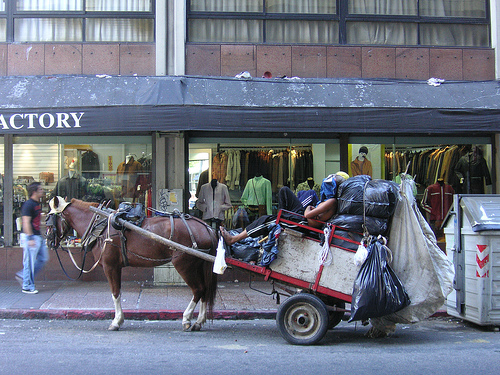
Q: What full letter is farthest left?
A: C.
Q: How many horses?
A: 1.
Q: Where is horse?
A: In front of the cart.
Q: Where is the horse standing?
A: The street.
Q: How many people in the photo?
A: 2.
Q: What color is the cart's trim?
A: Red.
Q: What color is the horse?
A: Brown.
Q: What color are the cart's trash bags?
A: Black.